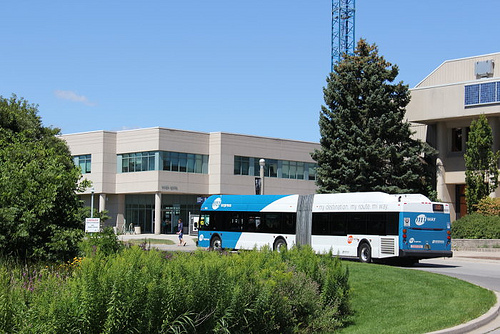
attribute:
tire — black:
[356, 237, 371, 262]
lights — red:
[400, 224, 458, 244]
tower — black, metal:
[329, 2, 359, 96]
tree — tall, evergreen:
[307, 37, 438, 200]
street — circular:
[111, 232, 498, 331]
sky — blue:
[33, 11, 313, 113]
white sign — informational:
[84, 214, 101, 234]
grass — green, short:
[124, 244, 485, 332]